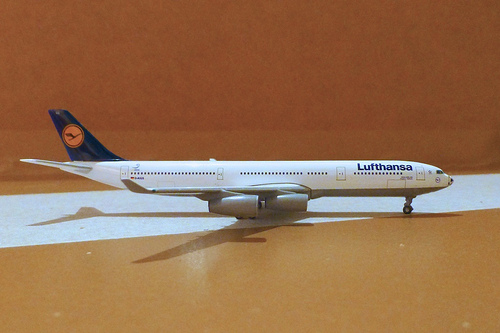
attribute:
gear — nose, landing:
[395, 202, 424, 221]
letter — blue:
[398, 162, 408, 172]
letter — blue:
[346, 158, 366, 178]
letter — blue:
[352, 160, 412, 173]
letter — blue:
[372, 159, 387, 175]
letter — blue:
[376, 159, 387, 171]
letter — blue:
[403, 158, 416, 172]